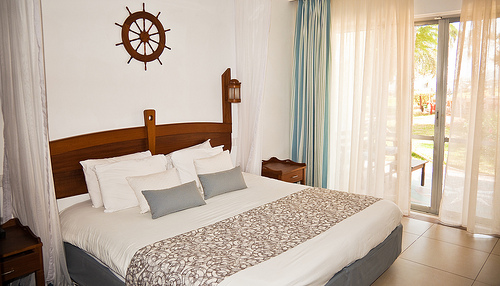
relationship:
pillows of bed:
[78, 139, 249, 213] [47, 69, 410, 282]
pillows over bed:
[78, 139, 249, 213] [47, 69, 410, 282]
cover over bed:
[50, 161, 401, 285] [47, 69, 410, 282]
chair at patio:
[381, 134, 431, 191] [358, 147, 499, 223]